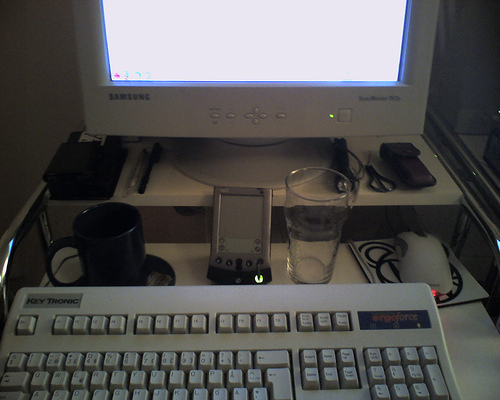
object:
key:
[189, 314, 208, 334]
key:
[332, 312, 351, 331]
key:
[299, 349, 318, 371]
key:
[336, 348, 356, 372]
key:
[216, 312, 235, 333]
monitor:
[65, 0, 448, 192]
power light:
[328, 112, 335, 120]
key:
[297, 312, 315, 332]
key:
[135, 315, 154, 334]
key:
[302, 367, 322, 390]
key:
[186, 369, 207, 392]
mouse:
[392, 229, 456, 298]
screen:
[101, 0, 414, 82]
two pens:
[124, 142, 165, 196]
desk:
[44, 132, 463, 209]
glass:
[281, 165, 355, 285]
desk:
[4, 237, 499, 397]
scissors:
[360, 146, 397, 193]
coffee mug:
[41, 201, 149, 289]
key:
[314, 312, 334, 332]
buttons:
[275, 112, 287, 119]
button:
[337, 107, 353, 123]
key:
[270, 313, 289, 332]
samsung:
[108, 91, 151, 101]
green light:
[254, 274, 264, 284]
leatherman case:
[379, 141, 438, 188]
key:
[171, 314, 189, 333]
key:
[52, 314, 73, 334]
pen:
[135, 142, 163, 195]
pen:
[327, 134, 358, 194]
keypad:
[1, 280, 463, 399]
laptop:
[2, 0, 470, 398]